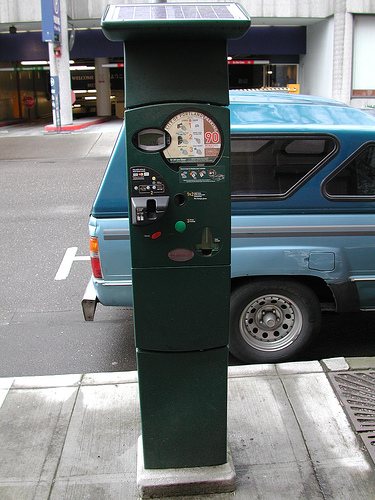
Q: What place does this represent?
A: It represents the street.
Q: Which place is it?
A: It is a street.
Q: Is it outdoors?
A: Yes, it is outdoors.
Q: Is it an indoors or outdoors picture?
A: It is outdoors.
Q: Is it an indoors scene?
A: No, it is outdoors.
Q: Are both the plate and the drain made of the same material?
A: Yes, both the plate and the drain are made of metal.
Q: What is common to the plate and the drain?
A: The material, both the plate and the drain are metallic.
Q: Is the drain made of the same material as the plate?
A: Yes, both the drain and the plate are made of metal.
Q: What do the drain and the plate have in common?
A: The material, both the drain and the plate are metallic.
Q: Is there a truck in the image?
A: Yes, there is a truck.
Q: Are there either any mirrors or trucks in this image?
A: Yes, there is a truck.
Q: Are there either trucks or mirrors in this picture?
A: Yes, there is a truck.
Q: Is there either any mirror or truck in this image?
A: Yes, there is a truck.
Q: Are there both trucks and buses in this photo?
A: No, there is a truck but no buses.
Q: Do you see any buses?
A: No, there are no buses.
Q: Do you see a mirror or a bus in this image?
A: No, there are no buses or mirrors.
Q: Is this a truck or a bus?
A: This is a truck.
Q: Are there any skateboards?
A: No, there are no skateboards.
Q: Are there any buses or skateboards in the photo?
A: No, there are no skateboards or buses.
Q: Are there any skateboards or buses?
A: No, there are no skateboards or buses.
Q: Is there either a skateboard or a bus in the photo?
A: No, there are no skateboards or buses.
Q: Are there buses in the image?
A: No, there are no buses.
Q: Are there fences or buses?
A: No, there are no buses or fences.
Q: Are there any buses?
A: No, there are no buses.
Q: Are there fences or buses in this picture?
A: No, there are no buses or fences.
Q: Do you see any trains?
A: No, there are no trains.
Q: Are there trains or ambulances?
A: No, there are no trains or ambulances.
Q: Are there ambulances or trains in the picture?
A: No, there are no trains or ambulances.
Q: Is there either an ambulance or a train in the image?
A: No, there are no trains or ambulances.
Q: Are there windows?
A: Yes, there is a window.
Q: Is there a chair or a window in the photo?
A: Yes, there is a window.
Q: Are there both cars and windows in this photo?
A: Yes, there are both a window and a car.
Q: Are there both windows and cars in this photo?
A: Yes, there are both a window and a car.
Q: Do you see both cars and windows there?
A: Yes, there are both a window and a car.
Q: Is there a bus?
A: No, there are no buses.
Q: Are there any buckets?
A: No, there are no buckets.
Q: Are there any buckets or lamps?
A: No, there are no buckets or lamps.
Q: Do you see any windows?
A: Yes, there is a window.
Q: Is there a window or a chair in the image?
A: Yes, there is a window.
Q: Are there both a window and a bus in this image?
A: No, there is a window but no buses.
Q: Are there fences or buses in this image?
A: No, there are no buses or fences.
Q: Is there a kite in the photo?
A: No, there are no kites.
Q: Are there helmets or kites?
A: No, there are no kites or helmets.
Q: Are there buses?
A: No, there are no buses.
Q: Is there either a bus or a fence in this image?
A: No, there are no buses or fences.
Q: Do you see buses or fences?
A: No, there are no buses or fences.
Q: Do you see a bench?
A: No, there are no benches.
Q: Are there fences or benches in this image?
A: No, there are no benches or fences.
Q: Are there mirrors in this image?
A: No, there are no mirrors.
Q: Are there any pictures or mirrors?
A: No, there are no mirrors or pictures.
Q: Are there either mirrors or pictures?
A: No, there are no mirrors or pictures.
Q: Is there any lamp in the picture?
A: No, there are no lamps.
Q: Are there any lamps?
A: No, there are no lamps.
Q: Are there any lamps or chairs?
A: No, there are no lamps or chairs.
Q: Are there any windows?
A: Yes, there is a window.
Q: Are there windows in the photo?
A: Yes, there is a window.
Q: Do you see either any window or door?
A: Yes, there is a window.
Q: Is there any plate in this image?
A: Yes, there is a plate.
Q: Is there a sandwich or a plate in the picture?
A: Yes, there is a plate.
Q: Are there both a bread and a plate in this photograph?
A: No, there is a plate but no breads.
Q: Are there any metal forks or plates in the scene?
A: Yes, there is a metal plate.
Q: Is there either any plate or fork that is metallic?
A: Yes, the plate is metallic.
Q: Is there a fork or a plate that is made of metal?
A: Yes, the plate is made of metal.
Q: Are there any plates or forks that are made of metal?
A: Yes, the plate is made of metal.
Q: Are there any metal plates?
A: Yes, there is a metal plate.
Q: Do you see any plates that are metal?
A: Yes, there is a metal plate.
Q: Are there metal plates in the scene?
A: Yes, there is a metal plate.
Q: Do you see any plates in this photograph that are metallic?
A: Yes, there is a plate that is metallic.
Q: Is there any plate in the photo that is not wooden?
A: Yes, there is a metallic plate.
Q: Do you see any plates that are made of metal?
A: Yes, there is a plate that is made of metal.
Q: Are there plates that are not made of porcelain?
A: Yes, there is a plate that is made of metal.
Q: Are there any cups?
A: No, there are no cups.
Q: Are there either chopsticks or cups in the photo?
A: No, there are no cups or chopsticks.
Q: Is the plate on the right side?
A: Yes, the plate is on the right of the image.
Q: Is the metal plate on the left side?
A: No, the plate is on the right of the image.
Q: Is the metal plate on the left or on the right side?
A: The plate is on the right of the image.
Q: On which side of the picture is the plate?
A: The plate is on the right of the image.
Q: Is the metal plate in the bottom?
A: Yes, the plate is in the bottom of the image.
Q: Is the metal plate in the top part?
A: No, the plate is in the bottom of the image.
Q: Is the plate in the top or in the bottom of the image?
A: The plate is in the bottom of the image.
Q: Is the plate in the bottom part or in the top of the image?
A: The plate is in the bottom of the image.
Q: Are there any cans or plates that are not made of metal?
A: No, there is a plate but it is made of metal.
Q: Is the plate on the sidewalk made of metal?
A: Yes, the plate is made of metal.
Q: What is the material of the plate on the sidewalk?
A: The plate is made of metal.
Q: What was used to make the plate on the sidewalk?
A: The plate is made of metal.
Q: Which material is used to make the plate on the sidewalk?
A: The plate is made of metal.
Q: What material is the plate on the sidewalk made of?
A: The plate is made of metal.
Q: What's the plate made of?
A: The plate is made of metal.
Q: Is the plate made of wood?
A: No, the plate is made of metal.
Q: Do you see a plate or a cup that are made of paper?
A: No, there is a plate but it is made of metal.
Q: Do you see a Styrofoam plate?
A: No, there is a plate but it is made of metal.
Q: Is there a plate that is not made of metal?
A: No, there is a plate but it is made of metal.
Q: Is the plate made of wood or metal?
A: The plate is made of metal.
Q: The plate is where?
A: The plate is on the sidewalk.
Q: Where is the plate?
A: The plate is on the sidewalk.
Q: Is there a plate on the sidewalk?
A: Yes, there is a plate on the sidewalk.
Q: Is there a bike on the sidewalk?
A: No, there is a plate on the sidewalk.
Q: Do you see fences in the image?
A: No, there are no fences.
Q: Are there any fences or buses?
A: No, there are no fences or buses.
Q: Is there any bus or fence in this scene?
A: No, there are no fences or buses.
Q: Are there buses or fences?
A: No, there are no fences or buses.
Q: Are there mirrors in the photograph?
A: No, there are no mirrors.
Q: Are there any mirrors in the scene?
A: No, there are no mirrors.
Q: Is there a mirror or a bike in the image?
A: No, there are no mirrors or bikes.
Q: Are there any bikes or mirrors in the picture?
A: No, there are no mirrors or bikes.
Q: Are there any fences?
A: No, there are no fences.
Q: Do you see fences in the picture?
A: No, there are no fences.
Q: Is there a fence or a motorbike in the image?
A: No, there are no fences or motorcycles.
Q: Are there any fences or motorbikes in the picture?
A: No, there are no fences or motorbikes.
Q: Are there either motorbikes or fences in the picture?
A: No, there are no fences or motorbikes.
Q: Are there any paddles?
A: No, there are no paddles.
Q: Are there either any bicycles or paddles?
A: No, there are no paddles or bicycles.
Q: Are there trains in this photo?
A: No, there are no trains.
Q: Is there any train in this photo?
A: No, there are no trains.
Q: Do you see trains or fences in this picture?
A: No, there are no trains or fences.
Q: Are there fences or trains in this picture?
A: No, there are no trains or fences.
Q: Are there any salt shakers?
A: No, there are no salt shakers.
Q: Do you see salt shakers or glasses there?
A: No, there are no salt shakers or glasses.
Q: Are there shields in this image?
A: No, there are no shields.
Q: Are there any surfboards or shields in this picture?
A: No, there are no shields or surfboards.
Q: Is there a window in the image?
A: Yes, there are windows.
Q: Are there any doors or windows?
A: Yes, there are windows.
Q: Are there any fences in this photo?
A: No, there are no fences.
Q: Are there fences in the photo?
A: No, there are no fences.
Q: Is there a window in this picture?
A: Yes, there is a window.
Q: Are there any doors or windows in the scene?
A: Yes, there is a window.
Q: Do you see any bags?
A: No, there are no bags.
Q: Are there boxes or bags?
A: No, there are no bags or boxes.